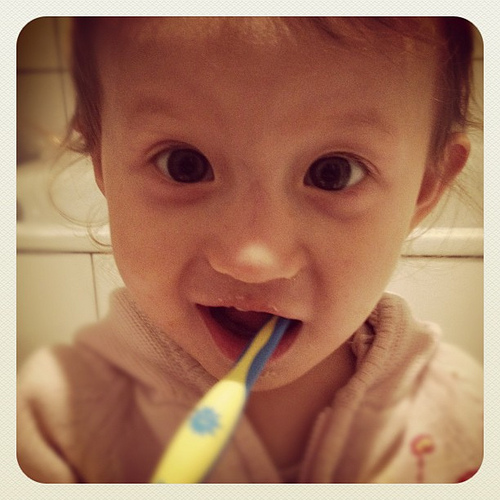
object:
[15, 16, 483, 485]
child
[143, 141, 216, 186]
eye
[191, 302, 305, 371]
mouth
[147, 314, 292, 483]
brush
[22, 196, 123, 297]
counter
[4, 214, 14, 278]
pattern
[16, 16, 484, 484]
kid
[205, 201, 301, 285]
nose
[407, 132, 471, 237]
ear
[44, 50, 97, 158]
bang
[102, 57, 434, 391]
face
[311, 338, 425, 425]
piece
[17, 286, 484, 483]
robe